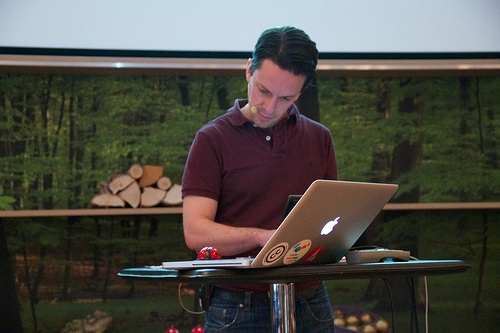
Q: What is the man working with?
A: The man is working with a computer.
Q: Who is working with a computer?
A: A man is working with a computer.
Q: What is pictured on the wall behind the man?
A: Trees are pictured on the wall.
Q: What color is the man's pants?
A: The man's pants are colored blue.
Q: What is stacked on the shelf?
A: Wood is stacked on the shelf.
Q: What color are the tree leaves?
A: The leaves are colored green.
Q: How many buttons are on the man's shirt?
A: The shirt has one button.